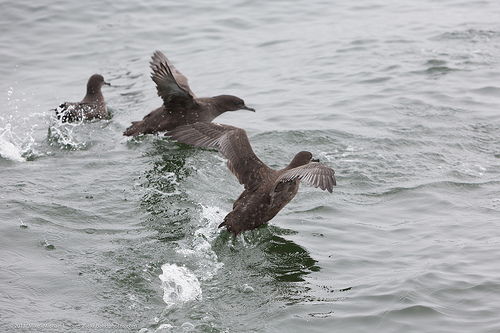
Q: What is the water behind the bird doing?
A: Splashing.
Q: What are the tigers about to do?
A: Fly.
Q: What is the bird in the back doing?
A: Sitting in the water.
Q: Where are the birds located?
A: In the water.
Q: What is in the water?
A: Ripples.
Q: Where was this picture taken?
A: Ocean.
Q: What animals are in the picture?
A: Birds.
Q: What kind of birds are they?
A: Seagulls.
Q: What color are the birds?
A: Brown.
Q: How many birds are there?
A: Three.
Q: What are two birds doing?
A: Flying.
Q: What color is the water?
A: Green.